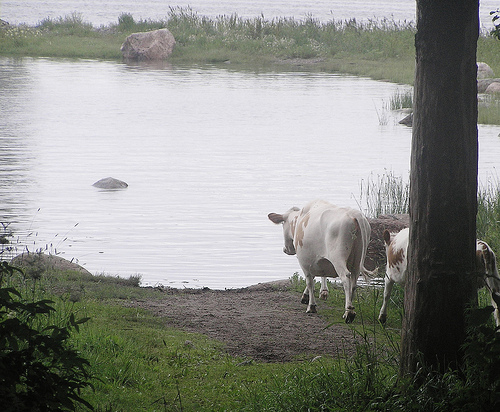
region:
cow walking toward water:
[272, 186, 372, 332]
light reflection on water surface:
[182, 137, 258, 246]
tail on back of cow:
[349, 216, 379, 298]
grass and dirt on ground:
[153, 305, 249, 379]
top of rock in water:
[80, 170, 132, 201]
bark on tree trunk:
[398, 179, 462, 347]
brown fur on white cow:
[379, 239, 408, 274]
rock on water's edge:
[105, 24, 181, 72]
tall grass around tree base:
[317, 333, 429, 405]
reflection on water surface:
[7, 66, 37, 175]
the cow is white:
[256, 178, 471, 386]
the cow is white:
[270, 182, 388, 339]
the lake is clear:
[105, 112, 435, 323]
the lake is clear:
[175, 50, 287, 221]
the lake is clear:
[100, 90, 294, 270]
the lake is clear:
[140, 42, 244, 133]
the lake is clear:
[126, 122, 258, 234]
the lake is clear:
[115, 62, 263, 197]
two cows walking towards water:
[213, 164, 488, 369]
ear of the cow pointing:
[260, 197, 311, 222]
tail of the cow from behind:
[320, 207, 375, 333]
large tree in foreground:
[387, 0, 497, 371]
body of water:
[20, 60, 423, 315]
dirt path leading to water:
[185, 285, 406, 400]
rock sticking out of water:
[60, 115, 190, 225]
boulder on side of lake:
[100, 28, 201, 79]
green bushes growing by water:
[80, 15, 382, 60]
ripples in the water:
[71, 207, 291, 272]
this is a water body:
[173, 110, 228, 186]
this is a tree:
[406, 23, 481, 270]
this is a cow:
[281, 199, 369, 308]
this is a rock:
[121, 30, 161, 54]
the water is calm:
[136, 123, 192, 173]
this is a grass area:
[103, 322, 180, 388]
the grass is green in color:
[126, 338, 179, 386]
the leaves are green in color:
[22, 289, 86, 394]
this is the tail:
[353, 215, 374, 279]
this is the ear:
[266, 208, 281, 230]